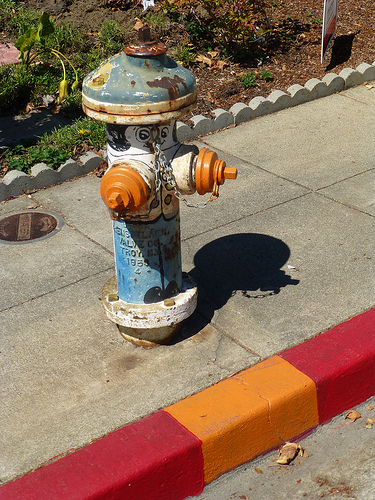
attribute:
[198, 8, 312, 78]
dirt — brown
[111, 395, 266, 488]
paints —    red and yellow 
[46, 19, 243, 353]
hydrant —  very funny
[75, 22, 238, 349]
hydrant —  rusty, blue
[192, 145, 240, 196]
yellow cap —  metal,  yellow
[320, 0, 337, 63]
sign — small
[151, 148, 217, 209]
chain —  small,  silver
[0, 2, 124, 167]
grass —  some,  ground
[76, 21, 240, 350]
fire hydrant — yellow, blue, white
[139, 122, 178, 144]
eyes — drawn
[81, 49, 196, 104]
cap — light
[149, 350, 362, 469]
curb — red, orange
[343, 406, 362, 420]
leaves —  some,  dry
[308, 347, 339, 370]
paint — red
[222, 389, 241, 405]
paint — yellow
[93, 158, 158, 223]
side — orange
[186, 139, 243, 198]
side — orange